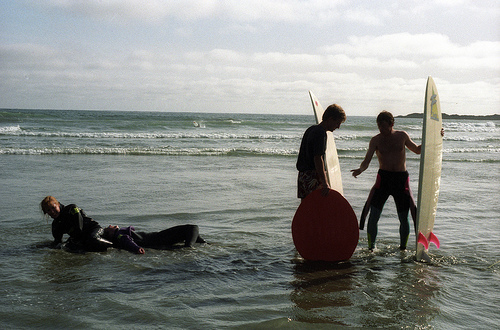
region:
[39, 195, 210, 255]
Two people lying in the water.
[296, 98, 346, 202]
A man carrying an egg shaped object in the water.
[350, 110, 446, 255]
A man with a wetsuit half on.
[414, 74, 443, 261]
A white surfboard with pink fins on it.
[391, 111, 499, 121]
Land in the distance.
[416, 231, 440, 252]
Two pink fins on a surfboard.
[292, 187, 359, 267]
An egg shaped object in the water.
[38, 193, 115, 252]
A woman lying in the water.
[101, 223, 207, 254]
A person with black pants on lying in the water.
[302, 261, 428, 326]
Ripples in the water in front of two men.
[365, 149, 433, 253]
man not wearing the top of his wetsuit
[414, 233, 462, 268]
neon pink fins on the surfboard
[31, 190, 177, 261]
person laying in the water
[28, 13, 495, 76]
sky is bright with clouds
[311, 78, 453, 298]
two surfboards standing up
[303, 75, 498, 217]
underneath of two surfboards are white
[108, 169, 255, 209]
water is calm and waveless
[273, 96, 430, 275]
two surfers standing in the water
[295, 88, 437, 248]
the surfers are men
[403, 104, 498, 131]
land behind the surfboard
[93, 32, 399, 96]
cloudy blue skies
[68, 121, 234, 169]
two smal waves in the water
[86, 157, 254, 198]
green and blue ocean water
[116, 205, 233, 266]
a woman laying down on the water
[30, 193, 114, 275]
a woman fell into the water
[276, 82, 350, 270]
a man standing with a board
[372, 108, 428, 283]
a man with his wetsit on his hips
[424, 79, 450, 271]
a white surfboard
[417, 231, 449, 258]
pink fins on the surfboard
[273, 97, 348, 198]
man looking down at water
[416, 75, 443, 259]
A white and pink surfboard.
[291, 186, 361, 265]
A red boogie board.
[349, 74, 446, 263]
A man holding a surfboard.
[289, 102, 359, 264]
A man holding a boogie board.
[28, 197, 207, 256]
Two people in the water.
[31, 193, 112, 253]
A lady in a wet suit.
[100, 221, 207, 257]
A man in a wet suit.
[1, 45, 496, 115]
A white cloudy sky.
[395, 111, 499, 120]
A mountain by the sea.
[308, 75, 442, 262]
Two white surfboards in the water.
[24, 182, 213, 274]
Two surfers lay in the water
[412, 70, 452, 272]
A white surfboard with pink fins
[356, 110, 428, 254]
A man in a black wetsuit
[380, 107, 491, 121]
Mountains in the distance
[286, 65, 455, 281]
The men are standing in the water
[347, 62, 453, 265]
The man is holding the surfboard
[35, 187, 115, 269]
the girl is wearing a black wetsuit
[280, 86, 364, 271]
The man is holding a round red boogie board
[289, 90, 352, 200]
The man has a black shirt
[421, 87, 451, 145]
A yellow and blue logo on the surfboard